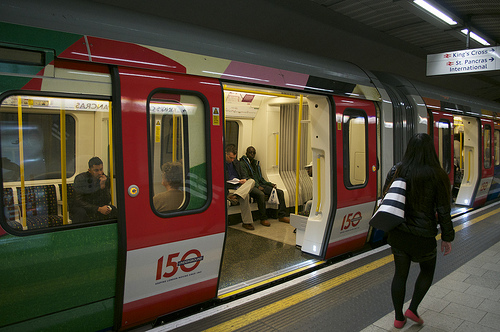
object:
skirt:
[387, 234, 437, 263]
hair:
[394, 132, 442, 204]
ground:
[429, 146, 466, 191]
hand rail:
[59, 107, 69, 224]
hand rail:
[107, 101, 115, 207]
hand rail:
[16, 95, 28, 229]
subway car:
[0, 0, 500, 332]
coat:
[382, 161, 456, 256]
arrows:
[488, 47, 495, 52]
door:
[114, 66, 229, 332]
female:
[369, 133, 456, 329]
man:
[218, 143, 256, 230]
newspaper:
[226, 177, 240, 184]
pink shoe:
[404, 308, 423, 324]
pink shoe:
[391, 315, 407, 329]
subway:
[1, 0, 496, 328]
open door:
[215, 82, 335, 300]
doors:
[322, 93, 378, 262]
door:
[429, 110, 455, 192]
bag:
[367, 163, 408, 229]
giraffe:
[152, 248, 204, 285]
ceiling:
[99, 0, 498, 91]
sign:
[425, 46, 500, 77]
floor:
[208, 95, 255, 147]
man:
[239, 146, 291, 227]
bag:
[268, 187, 280, 205]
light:
[409, 0, 460, 27]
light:
[459, 28, 491, 47]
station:
[133, 14, 499, 332]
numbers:
[155, 249, 203, 280]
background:
[124, 230, 225, 303]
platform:
[130, 190, 500, 332]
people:
[69, 155, 190, 223]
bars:
[294, 94, 303, 215]